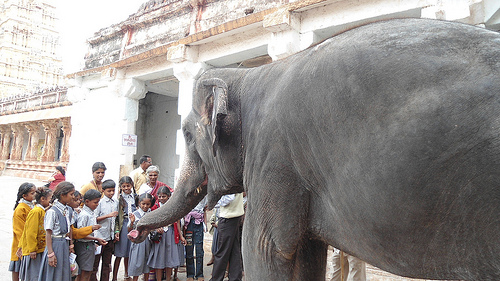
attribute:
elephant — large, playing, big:
[153, 27, 465, 265]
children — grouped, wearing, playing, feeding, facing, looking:
[37, 143, 173, 248]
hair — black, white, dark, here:
[46, 182, 83, 197]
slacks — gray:
[75, 242, 107, 277]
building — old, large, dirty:
[61, 19, 292, 157]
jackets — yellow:
[15, 204, 59, 243]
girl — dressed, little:
[109, 168, 141, 201]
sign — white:
[100, 130, 159, 158]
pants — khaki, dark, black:
[90, 232, 155, 275]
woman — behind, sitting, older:
[139, 156, 172, 180]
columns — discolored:
[8, 86, 71, 166]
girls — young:
[25, 169, 135, 245]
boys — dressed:
[68, 185, 117, 234]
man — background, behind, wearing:
[132, 149, 166, 169]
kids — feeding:
[41, 165, 170, 235]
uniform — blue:
[55, 200, 77, 263]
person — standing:
[65, 159, 95, 192]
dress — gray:
[33, 230, 83, 280]